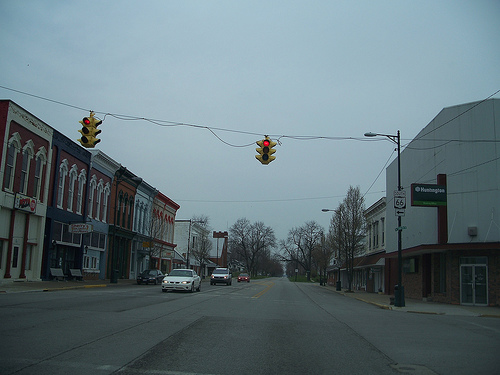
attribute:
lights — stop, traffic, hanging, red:
[76, 111, 278, 166]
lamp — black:
[365, 130, 406, 307]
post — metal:
[396, 129, 405, 308]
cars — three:
[164, 268, 252, 294]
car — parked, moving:
[137, 268, 168, 288]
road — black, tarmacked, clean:
[0, 275, 500, 374]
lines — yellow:
[248, 275, 287, 301]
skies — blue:
[3, 1, 500, 275]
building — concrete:
[383, 99, 499, 314]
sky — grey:
[2, 1, 498, 252]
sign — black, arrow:
[394, 190, 408, 209]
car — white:
[163, 268, 201, 294]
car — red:
[238, 272, 250, 286]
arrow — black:
[395, 210, 405, 216]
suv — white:
[211, 267, 231, 286]